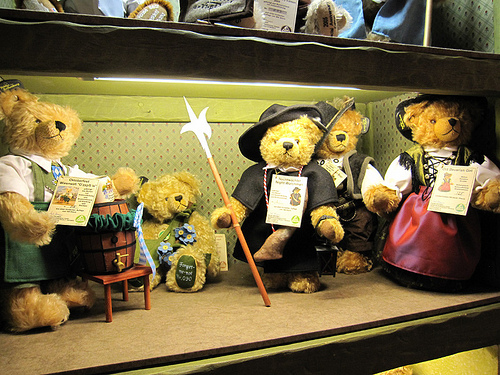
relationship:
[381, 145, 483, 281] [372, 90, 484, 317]
dress on bear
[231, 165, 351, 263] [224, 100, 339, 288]
jacket on bear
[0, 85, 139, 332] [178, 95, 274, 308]
bear holding pole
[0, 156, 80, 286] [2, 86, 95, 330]
jumper on bear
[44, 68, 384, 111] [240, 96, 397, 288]
light above bears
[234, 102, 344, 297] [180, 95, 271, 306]
bear holding pole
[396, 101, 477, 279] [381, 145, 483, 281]
bear wearing dress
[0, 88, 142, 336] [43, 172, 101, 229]
teddy holding paper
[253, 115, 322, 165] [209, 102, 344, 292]
head on tedbear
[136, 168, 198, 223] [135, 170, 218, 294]
head on tedbear